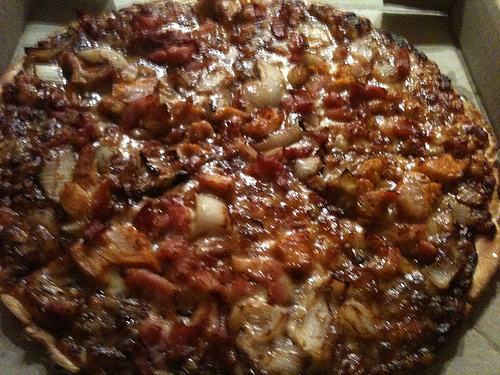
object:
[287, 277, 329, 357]
onions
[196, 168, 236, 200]
ham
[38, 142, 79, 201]
onion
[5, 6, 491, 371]
pizza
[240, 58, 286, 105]
cheese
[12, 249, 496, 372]
bottom slice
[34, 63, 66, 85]
onion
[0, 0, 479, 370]
crust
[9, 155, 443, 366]
part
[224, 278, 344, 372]
area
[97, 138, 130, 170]
onion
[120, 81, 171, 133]
ham